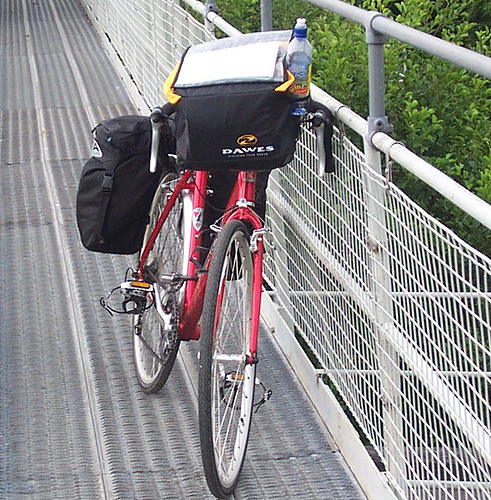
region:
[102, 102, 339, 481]
a pink bike on a bridge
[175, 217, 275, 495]
black tries on a rim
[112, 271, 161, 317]
foot petals with straps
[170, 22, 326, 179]
coller on handle bars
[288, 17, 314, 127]
water bottle in a holder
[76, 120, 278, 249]
a black suit case on the back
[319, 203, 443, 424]
wire screen on a bridge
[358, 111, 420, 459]
white metal pipe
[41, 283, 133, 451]
metal on the roadway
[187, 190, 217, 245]
logo on pink bike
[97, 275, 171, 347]
bicycle pedal on the left of the picture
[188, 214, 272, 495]
the front bicycle wheel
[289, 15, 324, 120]
water bottle on the handle bars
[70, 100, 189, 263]
plack back at the back of the bike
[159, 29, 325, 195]
open bag on bicycle handle bars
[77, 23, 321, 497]
bicycle leaning against a fence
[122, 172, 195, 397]
back wheel of the bicycle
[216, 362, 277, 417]
bike pedal on the right of the picture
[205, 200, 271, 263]
front bike brakes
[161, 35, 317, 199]
open bag with insignia on bars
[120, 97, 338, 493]
A red colored bicycle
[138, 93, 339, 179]
Handlebars on a bicycle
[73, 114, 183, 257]
A black bag on a bike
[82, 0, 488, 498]
A long white fence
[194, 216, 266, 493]
Wheel on a bicycle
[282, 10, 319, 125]
Water bottle full of water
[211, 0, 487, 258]
Green leaves on trees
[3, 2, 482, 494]
A bicycle on a bridge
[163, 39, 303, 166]
Black bag on front of the bike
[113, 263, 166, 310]
A peddle on the bicycle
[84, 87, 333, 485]
red bike laying by fence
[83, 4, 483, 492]
fence is white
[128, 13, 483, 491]
fence is on bridge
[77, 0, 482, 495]
fence is metal and slightly rusted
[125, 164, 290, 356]
red bike parked on bridge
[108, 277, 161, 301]
pedal of red bike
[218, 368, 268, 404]
pedal of red bike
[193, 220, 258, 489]
black tire of bike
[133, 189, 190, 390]
black tire of bike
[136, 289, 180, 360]
black chain of bike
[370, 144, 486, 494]
The gate is the color white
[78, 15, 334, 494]
The bike is standing on the gate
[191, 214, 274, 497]
The front tire of the bike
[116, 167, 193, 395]
The back tire of the bike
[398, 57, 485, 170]
The leaves on the bush are green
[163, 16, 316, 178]
The lunch box on the bike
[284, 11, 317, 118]
The water bottle on the side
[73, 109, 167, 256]
The backpack of the bike is clear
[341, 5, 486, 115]
The pole on the gate is gray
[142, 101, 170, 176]
The handle on the bike